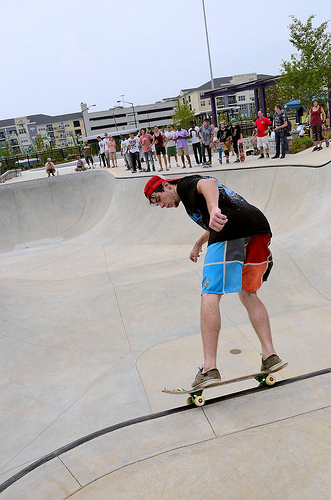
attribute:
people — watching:
[106, 120, 326, 182]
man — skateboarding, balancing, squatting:
[67, 159, 316, 395]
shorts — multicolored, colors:
[181, 228, 317, 315]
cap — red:
[132, 169, 176, 198]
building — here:
[16, 96, 176, 168]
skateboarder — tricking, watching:
[118, 141, 298, 410]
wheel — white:
[194, 399, 228, 416]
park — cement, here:
[2, 100, 304, 486]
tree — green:
[291, 27, 324, 107]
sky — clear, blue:
[42, 26, 177, 87]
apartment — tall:
[183, 37, 282, 154]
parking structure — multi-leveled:
[25, 88, 230, 153]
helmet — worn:
[312, 92, 326, 109]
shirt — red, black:
[249, 119, 267, 131]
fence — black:
[229, 111, 263, 140]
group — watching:
[121, 119, 295, 188]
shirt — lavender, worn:
[304, 108, 329, 137]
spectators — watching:
[82, 132, 313, 204]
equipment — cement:
[2, 162, 28, 238]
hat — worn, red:
[138, 167, 171, 199]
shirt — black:
[174, 180, 275, 234]